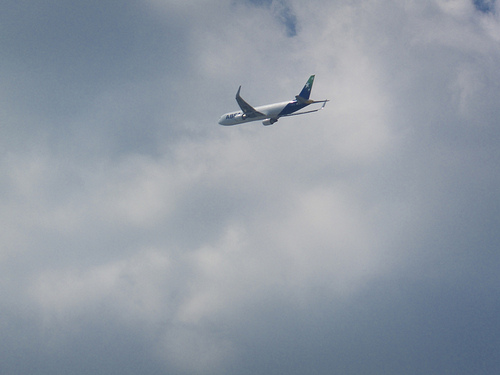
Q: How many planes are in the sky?
A: One.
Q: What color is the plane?
A: White.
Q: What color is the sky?
A: Gray.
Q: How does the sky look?
A: Cloudy.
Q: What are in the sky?
A: Clouds.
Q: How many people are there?
A: None.